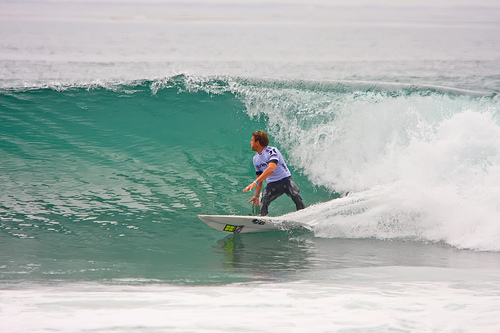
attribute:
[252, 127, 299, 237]
man — surfing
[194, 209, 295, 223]
surfboard — white, swimming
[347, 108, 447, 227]
wave — large, white, medium, blue, green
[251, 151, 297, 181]
shirt — blue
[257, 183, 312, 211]
pants — black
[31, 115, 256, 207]
water — green, splash, white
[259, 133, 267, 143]
hair — brown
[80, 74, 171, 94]
edge — curve